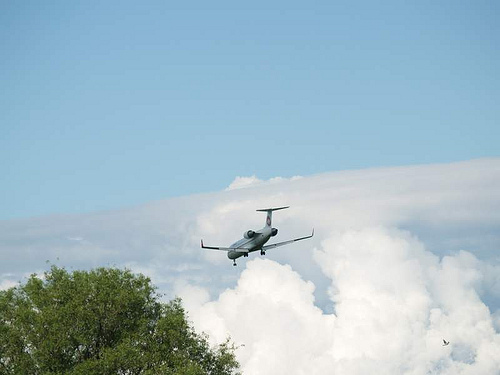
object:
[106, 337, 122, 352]
leaves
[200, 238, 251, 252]
winglet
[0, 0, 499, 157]
air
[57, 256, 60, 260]
leaves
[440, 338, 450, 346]
bird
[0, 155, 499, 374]
cloud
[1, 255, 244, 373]
tree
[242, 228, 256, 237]
engine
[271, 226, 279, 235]
engine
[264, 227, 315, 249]
wing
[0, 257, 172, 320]
top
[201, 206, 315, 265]
aircraft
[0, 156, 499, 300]
bank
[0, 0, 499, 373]
sky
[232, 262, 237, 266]
gear